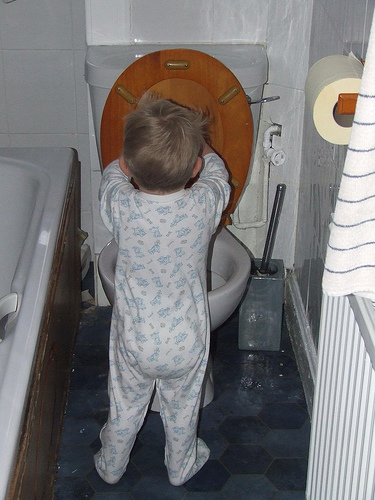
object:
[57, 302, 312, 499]
floor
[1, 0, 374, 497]
bathroom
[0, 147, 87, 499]
bath tub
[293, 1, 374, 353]
wall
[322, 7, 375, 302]
cloth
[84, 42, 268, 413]
toilet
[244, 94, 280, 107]
handle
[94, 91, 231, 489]
baby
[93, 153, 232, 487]
pajamas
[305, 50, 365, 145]
toilet paper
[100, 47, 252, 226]
toilet seat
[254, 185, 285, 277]
toilet brush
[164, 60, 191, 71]
rubber foot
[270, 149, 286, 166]
knob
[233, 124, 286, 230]
pipe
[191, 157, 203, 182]
ear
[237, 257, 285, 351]
box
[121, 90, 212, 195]
hair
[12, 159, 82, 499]
wood